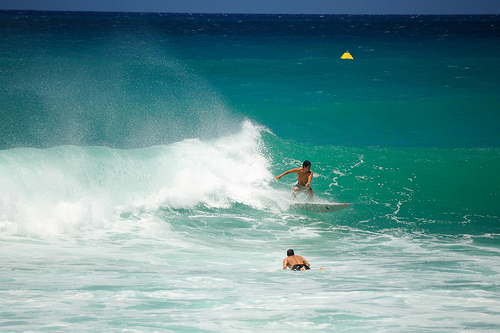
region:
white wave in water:
[35, 158, 66, 204]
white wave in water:
[89, 188, 117, 231]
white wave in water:
[170, 174, 210, 206]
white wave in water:
[213, 176, 239, 216]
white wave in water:
[250, 156, 282, 194]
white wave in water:
[241, 121, 271, 149]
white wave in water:
[9, 206, 46, 236]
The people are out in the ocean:
[20, 40, 450, 320]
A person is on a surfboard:
[222, 121, 417, 238]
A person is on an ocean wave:
[166, 118, 444, 239]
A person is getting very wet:
[156, 135, 421, 240]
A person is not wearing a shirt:
[177, 130, 449, 225]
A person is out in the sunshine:
[186, 125, 456, 247]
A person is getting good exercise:
[217, 103, 453, 229]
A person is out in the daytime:
[227, 123, 428, 238]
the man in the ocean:
[270, 245, 325, 277]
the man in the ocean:
[270, 155, 320, 202]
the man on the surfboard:
[271, 147, 352, 217]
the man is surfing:
[273, 150, 357, 220]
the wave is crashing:
[35, 144, 243, 236]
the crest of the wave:
[251, 118, 299, 155]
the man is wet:
[281, 242, 323, 277]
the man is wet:
[268, 154, 328, 206]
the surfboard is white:
[279, 180, 346, 223]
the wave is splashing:
[49, 190, 131, 246]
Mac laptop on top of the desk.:
[306, 58, 311, 140]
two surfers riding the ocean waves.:
[275, 155, 350, 275]